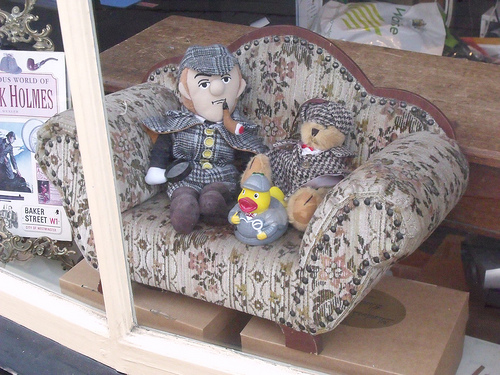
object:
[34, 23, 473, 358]
couch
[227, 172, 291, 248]
rubber ducky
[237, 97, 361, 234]
bear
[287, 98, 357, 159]
hat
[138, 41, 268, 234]
sherlock holmes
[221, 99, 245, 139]
pipe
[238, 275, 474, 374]
box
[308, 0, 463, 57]
bag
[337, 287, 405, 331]
sticker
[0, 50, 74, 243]
book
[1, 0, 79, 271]
book holder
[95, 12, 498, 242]
desk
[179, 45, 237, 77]
hat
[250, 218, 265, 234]
magnifying glass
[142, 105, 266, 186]
coat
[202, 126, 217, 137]
buton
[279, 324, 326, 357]
foot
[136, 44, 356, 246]
stuffed animals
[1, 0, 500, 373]
photo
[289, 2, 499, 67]
clutter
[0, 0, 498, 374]
window